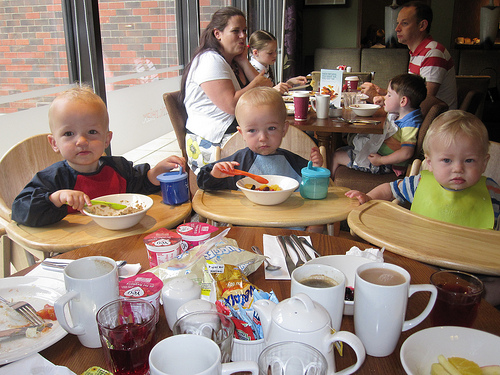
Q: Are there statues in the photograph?
A: No, there are no statues.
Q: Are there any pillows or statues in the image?
A: No, there are no statues or pillows.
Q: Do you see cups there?
A: Yes, there is a cup.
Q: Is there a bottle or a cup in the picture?
A: Yes, there is a cup.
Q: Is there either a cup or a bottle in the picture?
A: Yes, there is a cup.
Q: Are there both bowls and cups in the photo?
A: Yes, there are both a cup and a bowl.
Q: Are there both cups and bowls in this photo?
A: Yes, there are both a cup and a bowl.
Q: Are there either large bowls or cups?
A: Yes, there is a large cup.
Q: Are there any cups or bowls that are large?
A: Yes, the cup is large.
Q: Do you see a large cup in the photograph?
A: Yes, there is a large cup.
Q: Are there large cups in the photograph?
A: Yes, there is a large cup.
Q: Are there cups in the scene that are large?
A: Yes, there is a cup that is large.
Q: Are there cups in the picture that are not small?
A: Yes, there is a large cup.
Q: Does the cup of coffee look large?
A: Yes, the cup is large.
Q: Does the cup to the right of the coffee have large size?
A: Yes, the cup is large.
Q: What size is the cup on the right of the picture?
A: The cup is large.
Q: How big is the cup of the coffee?
A: The cup is large.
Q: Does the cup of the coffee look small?
A: No, the cup is large.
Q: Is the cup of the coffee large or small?
A: The cup is large.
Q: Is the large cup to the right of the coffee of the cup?
A: Yes, the cup is to the right of the coffee.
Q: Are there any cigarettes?
A: No, there are no cigarettes.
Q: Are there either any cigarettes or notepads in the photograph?
A: No, there are no cigarettes or notepads.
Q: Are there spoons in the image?
A: Yes, there is a spoon.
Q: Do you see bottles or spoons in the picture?
A: Yes, there is a spoon.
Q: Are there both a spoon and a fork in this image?
A: Yes, there are both a spoon and a fork.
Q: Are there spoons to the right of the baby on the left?
A: Yes, there is a spoon to the right of the baby.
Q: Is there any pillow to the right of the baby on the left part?
A: No, there is a spoon to the right of the baby.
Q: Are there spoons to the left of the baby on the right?
A: Yes, there is a spoon to the left of the baby.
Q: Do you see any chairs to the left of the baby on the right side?
A: No, there is a spoon to the left of the baby.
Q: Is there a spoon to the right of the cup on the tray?
A: No, the spoon is to the left of the cup.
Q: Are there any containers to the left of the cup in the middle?
A: No, there is a spoon to the left of the cup.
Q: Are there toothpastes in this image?
A: No, there are no toothpastes.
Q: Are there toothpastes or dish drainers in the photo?
A: No, there are no toothpastes or dish drainers.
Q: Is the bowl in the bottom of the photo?
A: No, the bowl is in the top of the image.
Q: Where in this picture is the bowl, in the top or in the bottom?
A: The bowl is in the top of the image.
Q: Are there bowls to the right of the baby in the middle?
A: Yes, there is a bowl to the right of the baby.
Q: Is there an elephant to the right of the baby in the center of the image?
A: No, there is a bowl to the right of the baby.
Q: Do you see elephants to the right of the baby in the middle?
A: No, there is a bowl to the right of the baby.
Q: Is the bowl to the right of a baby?
A: Yes, the bowl is to the right of a baby.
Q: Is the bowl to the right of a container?
A: No, the bowl is to the right of a baby.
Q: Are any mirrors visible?
A: No, there are no mirrors.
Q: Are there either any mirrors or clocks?
A: No, there are no mirrors or clocks.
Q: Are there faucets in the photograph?
A: No, there are no faucets.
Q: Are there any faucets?
A: No, there are no faucets.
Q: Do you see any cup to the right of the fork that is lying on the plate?
A: Yes, there are cups to the right of the fork.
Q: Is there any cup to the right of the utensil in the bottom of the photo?
A: Yes, there are cups to the right of the fork.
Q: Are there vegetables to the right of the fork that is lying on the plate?
A: No, there are cups to the right of the fork.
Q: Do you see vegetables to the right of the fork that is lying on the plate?
A: No, there are cups to the right of the fork.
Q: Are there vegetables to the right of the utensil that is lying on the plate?
A: No, there are cups to the right of the fork.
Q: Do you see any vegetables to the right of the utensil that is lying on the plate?
A: No, there are cups to the right of the fork.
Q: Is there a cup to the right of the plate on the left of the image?
A: Yes, there are cups to the right of the plate.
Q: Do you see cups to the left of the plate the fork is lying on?
A: No, the cups are to the right of the plate.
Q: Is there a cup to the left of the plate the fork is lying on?
A: No, the cups are to the right of the plate.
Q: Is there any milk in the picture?
A: Yes, there is milk.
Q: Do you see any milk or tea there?
A: Yes, there is milk.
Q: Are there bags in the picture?
A: No, there are no bags.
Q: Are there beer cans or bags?
A: No, there are no bags or beer cans.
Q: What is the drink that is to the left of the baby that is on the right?
A: The drink is milk.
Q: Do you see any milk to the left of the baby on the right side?
A: Yes, there is milk to the left of the baby.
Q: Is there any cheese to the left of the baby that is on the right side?
A: No, there is milk to the left of the baby.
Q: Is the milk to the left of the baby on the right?
A: Yes, the milk is to the left of the baby.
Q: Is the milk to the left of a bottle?
A: No, the milk is to the left of the baby.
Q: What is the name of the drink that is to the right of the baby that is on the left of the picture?
A: The drink is milk.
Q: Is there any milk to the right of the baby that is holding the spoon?
A: Yes, there is milk to the right of the baby.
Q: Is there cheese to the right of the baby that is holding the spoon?
A: No, there is milk to the right of the baby.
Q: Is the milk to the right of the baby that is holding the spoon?
A: Yes, the milk is to the right of the baby.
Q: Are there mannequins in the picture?
A: No, there are no mannequins.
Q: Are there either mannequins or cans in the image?
A: No, there are no mannequins or cans.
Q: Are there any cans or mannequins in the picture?
A: No, there are no mannequins or cans.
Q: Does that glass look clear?
A: Yes, the glass is clear.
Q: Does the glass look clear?
A: Yes, the glass is clear.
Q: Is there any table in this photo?
A: Yes, there is a table.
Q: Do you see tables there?
A: Yes, there is a table.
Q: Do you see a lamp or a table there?
A: Yes, there is a table.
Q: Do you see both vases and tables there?
A: No, there is a table but no vases.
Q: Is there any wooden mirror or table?
A: Yes, there is a wood table.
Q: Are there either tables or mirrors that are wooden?
A: Yes, the table is wooden.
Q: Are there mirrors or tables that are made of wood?
A: Yes, the table is made of wood.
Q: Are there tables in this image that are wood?
A: Yes, there is a wood table.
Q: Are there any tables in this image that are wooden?
A: Yes, there is a table that is wooden.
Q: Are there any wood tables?
A: Yes, there is a table that is made of wood.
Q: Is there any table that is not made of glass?
A: Yes, there is a table that is made of wood.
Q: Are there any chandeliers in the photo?
A: No, there are no chandeliers.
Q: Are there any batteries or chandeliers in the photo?
A: No, there are no chandeliers or batteries.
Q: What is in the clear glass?
A: The liquid is in the glass.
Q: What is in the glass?
A: The liquid is in the glass.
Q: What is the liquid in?
A: The liquid is in the glass.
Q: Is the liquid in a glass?
A: Yes, the liquid is in a glass.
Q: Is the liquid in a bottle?
A: No, the liquid is in a glass.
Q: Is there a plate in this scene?
A: Yes, there is a plate.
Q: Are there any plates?
A: Yes, there is a plate.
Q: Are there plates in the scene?
A: Yes, there is a plate.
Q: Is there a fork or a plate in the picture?
A: Yes, there is a plate.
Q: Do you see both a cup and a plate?
A: Yes, there are both a plate and a cup.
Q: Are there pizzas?
A: No, there are no pizzas.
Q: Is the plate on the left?
A: Yes, the plate is on the left of the image.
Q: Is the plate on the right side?
A: No, the plate is on the left of the image.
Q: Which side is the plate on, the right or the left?
A: The plate is on the left of the image.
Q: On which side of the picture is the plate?
A: The plate is on the left of the image.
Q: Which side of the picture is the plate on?
A: The plate is on the left of the image.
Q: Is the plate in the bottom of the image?
A: Yes, the plate is in the bottom of the image.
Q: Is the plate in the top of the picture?
A: No, the plate is in the bottom of the image.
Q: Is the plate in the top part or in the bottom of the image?
A: The plate is in the bottom of the image.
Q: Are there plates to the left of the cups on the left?
A: Yes, there is a plate to the left of the cups.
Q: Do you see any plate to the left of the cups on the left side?
A: Yes, there is a plate to the left of the cups.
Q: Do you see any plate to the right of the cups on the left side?
A: No, the plate is to the left of the cups.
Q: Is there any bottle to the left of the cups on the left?
A: No, there is a plate to the left of the cups.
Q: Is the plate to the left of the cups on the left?
A: Yes, the plate is to the left of the cups.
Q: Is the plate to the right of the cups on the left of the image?
A: No, the plate is to the left of the cups.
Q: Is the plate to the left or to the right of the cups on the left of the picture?
A: The plate is to the left of the cups.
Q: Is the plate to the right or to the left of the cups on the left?
A: The plate is to the left of the cups.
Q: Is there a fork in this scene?
A: Yes, there is a fork.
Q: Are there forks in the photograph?
A: Yes, there is a fork.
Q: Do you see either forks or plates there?
A: Yes, there is a fork.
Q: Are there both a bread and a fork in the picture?
A: No, there is a fork but no breads.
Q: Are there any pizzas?
A: No, there are no pizzas.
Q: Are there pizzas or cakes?
A: No, there are no pizzas or cakes.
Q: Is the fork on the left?
A: Yes, the fork is on the left of the image.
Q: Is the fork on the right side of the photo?
A: No, the fork is on the left of the image.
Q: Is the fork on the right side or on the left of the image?
A: The fork is on the left of the image.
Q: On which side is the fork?
A: The fork is on the left of the image.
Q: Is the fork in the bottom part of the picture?
A: Yes, the fork is in the bottom of the image.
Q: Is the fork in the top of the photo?
A: No, the fork is in the bottom of the image.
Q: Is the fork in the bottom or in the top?
A: The fork is in the bottom of the image.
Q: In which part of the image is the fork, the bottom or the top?
A: The fork is in the bottom of the image.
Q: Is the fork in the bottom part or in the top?
A: The fork is in the bottom of the image.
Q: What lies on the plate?
A: The fork lies on the plate.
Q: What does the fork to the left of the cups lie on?
A: The fork lies on the plate.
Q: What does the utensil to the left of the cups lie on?
A: The fork lies on the plate.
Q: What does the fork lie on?
A: The fork lies on the plate.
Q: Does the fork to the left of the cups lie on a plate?
A: Yes, the fork lies on a plate.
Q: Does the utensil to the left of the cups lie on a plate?
A: Yes, the fork lies on a plate.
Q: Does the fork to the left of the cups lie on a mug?
A: No, the fork lies on a plate.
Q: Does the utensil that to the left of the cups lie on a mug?
A: No, the fork lies on a plate.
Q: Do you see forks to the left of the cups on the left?
A: Yes, there is a fork to the left of the cups.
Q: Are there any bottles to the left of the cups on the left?
A: No, there is a fork to the left of the cups.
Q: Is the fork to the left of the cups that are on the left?
A: Yes, the fork is to the left of the cups.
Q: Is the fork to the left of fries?
A: No, the fork is to the left of the cups.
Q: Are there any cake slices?
A: No, there are no cake slices.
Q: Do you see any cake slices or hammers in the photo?
A: No, there are no cake slices or hammers.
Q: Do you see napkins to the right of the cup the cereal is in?
A: Yes, there is a napkin to the right of the cup.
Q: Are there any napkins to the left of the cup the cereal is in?
A: No, the napkin is to the right of the cup.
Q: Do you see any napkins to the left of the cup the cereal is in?
A: No, the napkin is to the right of the cup.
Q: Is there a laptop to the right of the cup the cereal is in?
A: No, there is a napkin to the right of the cup.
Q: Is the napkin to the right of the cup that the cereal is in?
A: Yes, the napkin is to the right of the cup.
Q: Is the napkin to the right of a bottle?
A: No, the napkin is to the right of the cup.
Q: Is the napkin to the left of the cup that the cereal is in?
A: No, the napkin is to the right of the cup.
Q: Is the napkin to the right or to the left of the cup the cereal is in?
A: The napkin is to the right of the cup.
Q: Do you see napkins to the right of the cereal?
A: Yes, there is a napkin to the right of the cereal.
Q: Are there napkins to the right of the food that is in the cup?
A: Yes, there is a napkin to the right of the cereal.